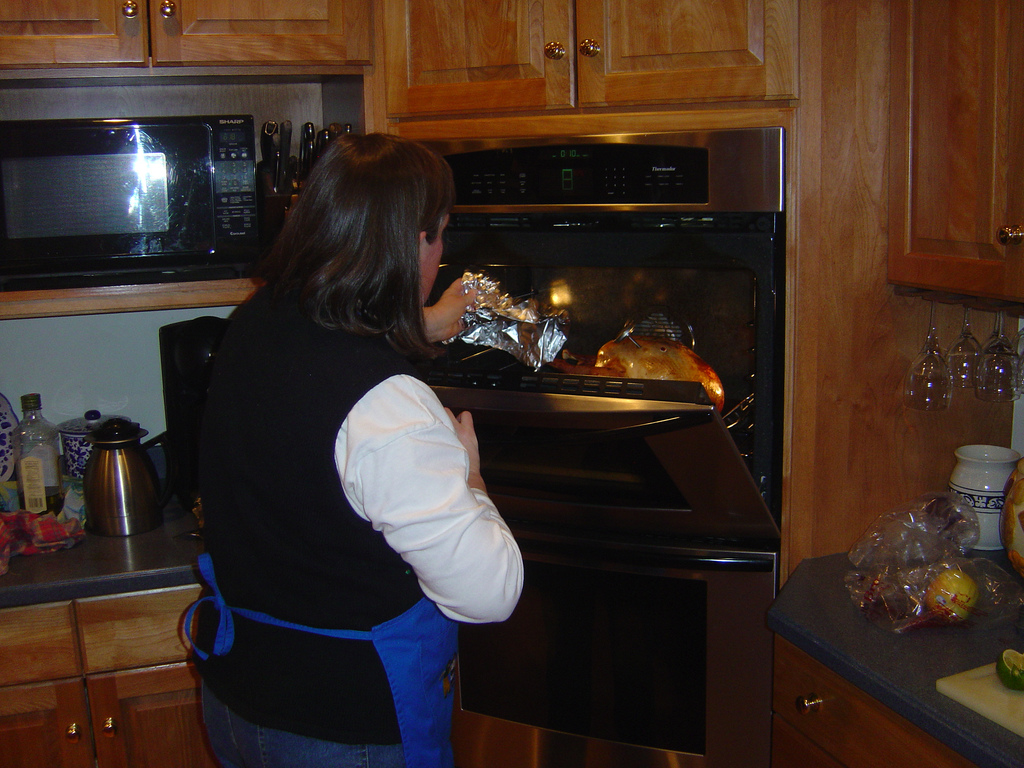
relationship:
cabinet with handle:
[10, 3, 372, 67] [96, 711, 120, 743]